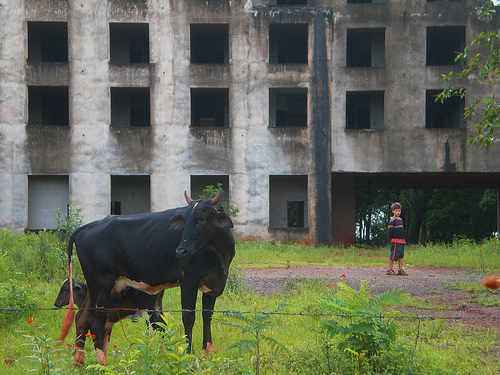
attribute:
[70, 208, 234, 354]
bull — black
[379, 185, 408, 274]
kid — black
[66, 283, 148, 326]
calf — small, facing left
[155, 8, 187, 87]
wall — old, marked, stone, long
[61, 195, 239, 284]
cow — baby, standing, brown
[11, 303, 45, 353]
flowers — red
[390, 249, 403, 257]
shorts — red, black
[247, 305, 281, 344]
bush — green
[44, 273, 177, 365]
cow — baby